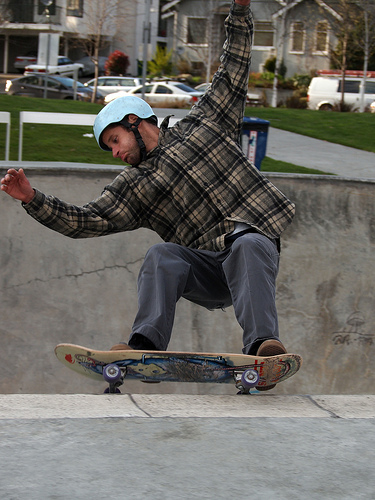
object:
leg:
[221, 227, 282, 340]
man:
[2, 0, 295, 357]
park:
[0, 1, 375, 500]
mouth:
[119, 147, 127, 162]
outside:
[0, 1, 375, 500]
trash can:
[240, 115, 270, 170]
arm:
[199, 0, 255, 124]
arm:
[29, 167, 137, 235]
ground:
[0, 69, 375, 500]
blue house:
[159, 1, 347, 88]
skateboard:
[54, 334, 301, 395]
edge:
[0, 391, 373, 403]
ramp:
[2, 177, 375, 397]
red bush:
[104, 50, 129, 77]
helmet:
[92, 96, 164, 169]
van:
[307, 75, 375, 116]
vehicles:
[3, 54, 264, 107]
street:
[0, 0, 375, 186]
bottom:
[71, 351, 235, 385]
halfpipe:
[0, 173, 375, 397]